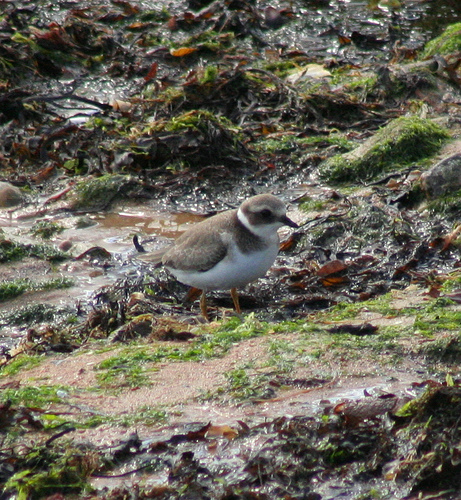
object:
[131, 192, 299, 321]
bird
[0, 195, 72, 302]
water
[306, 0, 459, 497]
ground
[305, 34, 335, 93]
water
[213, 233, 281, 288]
chest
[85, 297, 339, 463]
ground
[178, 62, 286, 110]
grass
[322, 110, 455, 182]
grass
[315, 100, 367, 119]
shades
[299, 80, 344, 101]
leaves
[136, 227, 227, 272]
right wing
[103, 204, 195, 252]
water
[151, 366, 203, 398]
no grass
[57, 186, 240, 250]
water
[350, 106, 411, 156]
ground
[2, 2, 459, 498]
muddy surface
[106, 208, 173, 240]
water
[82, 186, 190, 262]
puddle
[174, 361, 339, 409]
ground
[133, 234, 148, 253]
tail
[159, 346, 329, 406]
ground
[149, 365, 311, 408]
ground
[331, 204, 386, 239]
murky area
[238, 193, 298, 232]
head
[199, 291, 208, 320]
leg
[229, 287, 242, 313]
leg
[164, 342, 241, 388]
space